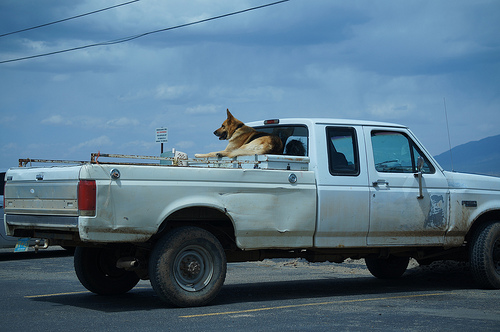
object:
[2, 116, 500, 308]
truck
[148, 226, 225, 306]
tire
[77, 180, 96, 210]
brake light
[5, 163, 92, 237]
rear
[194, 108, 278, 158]
dog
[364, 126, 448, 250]
door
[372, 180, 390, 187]
handle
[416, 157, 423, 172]
mirror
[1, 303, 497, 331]
ground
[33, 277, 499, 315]
shadow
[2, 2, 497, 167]
sky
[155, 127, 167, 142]
sign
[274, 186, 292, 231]
dent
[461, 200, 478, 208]
emblem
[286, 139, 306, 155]
person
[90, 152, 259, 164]
rail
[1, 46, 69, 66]
wire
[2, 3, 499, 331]
air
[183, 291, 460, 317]
line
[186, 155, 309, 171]
container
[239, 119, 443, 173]
top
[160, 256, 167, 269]
mud